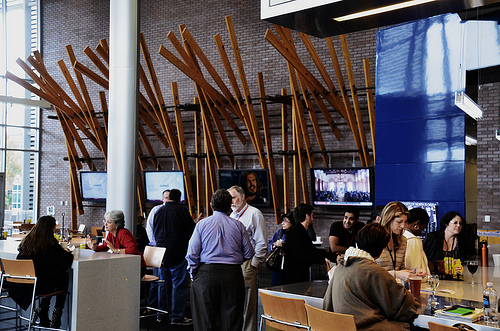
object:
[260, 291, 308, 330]
chair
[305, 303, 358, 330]
chair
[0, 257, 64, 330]
chair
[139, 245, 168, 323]
chair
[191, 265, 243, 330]
trousers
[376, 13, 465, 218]
board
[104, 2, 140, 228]
pole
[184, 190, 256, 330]
man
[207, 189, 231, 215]
hair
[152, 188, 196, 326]
man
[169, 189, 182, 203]
hair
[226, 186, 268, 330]
man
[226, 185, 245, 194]
hair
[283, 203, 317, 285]
man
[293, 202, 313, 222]
hair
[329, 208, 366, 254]
man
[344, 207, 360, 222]
hair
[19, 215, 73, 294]
woman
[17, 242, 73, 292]
shirt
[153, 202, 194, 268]
shirt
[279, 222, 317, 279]
shirt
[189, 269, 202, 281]
hand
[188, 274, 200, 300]
pocket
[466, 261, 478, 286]
glass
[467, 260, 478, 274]
wine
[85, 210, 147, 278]
woman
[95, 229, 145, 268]
shirt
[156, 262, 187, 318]
jeans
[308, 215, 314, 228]
beard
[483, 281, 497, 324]
water bottle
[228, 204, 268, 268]
dress shirt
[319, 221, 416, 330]
woman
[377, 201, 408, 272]
woman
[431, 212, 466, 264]
woman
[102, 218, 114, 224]
glasses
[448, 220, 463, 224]
glasses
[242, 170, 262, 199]
man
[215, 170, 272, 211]
television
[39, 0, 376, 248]
wall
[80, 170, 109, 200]
television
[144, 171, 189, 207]
television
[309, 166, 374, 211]
television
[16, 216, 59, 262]
hair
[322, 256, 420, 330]
coat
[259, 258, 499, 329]
desk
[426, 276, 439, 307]
glass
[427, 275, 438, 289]
water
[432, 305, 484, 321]
book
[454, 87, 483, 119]
light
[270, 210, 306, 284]
woman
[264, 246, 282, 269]
bag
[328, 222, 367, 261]
shirt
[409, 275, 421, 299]
glass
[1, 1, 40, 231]
windows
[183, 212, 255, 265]
shirt